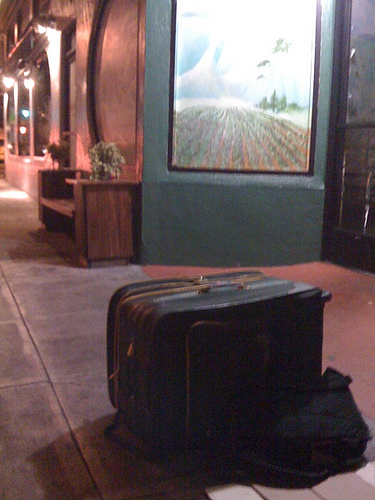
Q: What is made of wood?
A: Built in bench.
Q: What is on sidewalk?
A: Blue luggage.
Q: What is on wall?
A: Poster.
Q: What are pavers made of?
A: Grey concrete.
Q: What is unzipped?
A: Suitcase.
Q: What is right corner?
A: Large brown wooden door.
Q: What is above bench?
A: Section of recessed wall.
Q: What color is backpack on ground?
A: Black.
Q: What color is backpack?
A: Black.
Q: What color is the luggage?
A: Black.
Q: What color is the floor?
A: Red.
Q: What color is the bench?
A: Brown.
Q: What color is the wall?
A: Brown.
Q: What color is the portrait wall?
A: Blue.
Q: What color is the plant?
A: Green.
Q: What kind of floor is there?
A: Tiled.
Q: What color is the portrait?
A: Blue and green.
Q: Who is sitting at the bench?
A: No one.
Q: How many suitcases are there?
A: One.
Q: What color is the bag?
A: Black.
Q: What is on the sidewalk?
A: Luggage.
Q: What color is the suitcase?
A: Black.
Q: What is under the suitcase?
A: Wheels.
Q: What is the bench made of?
A: Wood.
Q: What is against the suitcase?
A: Backpack.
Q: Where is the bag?
A: Floor.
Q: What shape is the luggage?
A: Square.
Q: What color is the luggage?
A: Black.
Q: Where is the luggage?
A: On the sidewalk.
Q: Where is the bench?
A: Against the shop wall.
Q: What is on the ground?
A: Luggage.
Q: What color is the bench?
A: Brown.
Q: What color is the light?
A: Yellow.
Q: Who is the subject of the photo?
A: The luggage.